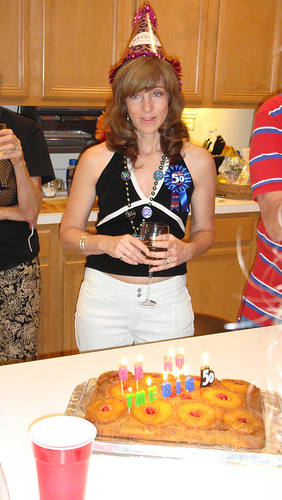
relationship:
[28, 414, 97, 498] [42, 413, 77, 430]
cup with inside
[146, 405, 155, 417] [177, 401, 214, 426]
cherry middle of pineapple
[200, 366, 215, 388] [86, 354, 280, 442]
50 on cake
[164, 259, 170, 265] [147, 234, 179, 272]
ring on left hand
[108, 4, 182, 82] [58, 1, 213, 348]
birthday hat on head of woman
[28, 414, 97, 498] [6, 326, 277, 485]
cup on top of table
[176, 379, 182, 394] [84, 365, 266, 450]
candle on top of birthday cake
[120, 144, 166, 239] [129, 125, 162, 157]
beads around neck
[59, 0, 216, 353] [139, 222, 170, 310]
girl holding glass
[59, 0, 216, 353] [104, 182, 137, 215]
girl wearing a shirt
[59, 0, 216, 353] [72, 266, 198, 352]
girl wearing pants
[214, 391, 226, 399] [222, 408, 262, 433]
cherry inside of slice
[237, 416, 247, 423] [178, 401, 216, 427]
cherry inside of slice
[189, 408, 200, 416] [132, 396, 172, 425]
cherry inside of slice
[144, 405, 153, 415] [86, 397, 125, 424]
cherry inside of slice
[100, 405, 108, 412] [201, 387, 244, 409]
cherry inside of slice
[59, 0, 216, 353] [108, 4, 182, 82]
girl wearing a birthday hat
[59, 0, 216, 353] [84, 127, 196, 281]
girl wearing a shirt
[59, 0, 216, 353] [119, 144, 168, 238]
girl wearing a necklace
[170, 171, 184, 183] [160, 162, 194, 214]
50 printed on ribbon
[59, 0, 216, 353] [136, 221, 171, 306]
girl holding glass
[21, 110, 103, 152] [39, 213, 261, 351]
toaster above cabinet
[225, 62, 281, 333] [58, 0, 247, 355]
person standing right of woman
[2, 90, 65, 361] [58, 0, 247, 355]
person standing left of woman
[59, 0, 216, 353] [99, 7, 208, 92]
girl wearing a hat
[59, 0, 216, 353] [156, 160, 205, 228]
girl wearing a ribbon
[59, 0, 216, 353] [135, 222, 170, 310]
girl holding glass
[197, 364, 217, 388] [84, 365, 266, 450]
candle on top of birthday cake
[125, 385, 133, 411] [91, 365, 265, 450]
candle on birthday cake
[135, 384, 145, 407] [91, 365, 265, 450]
candle on birthday cake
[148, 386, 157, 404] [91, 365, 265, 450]
candle on birthday cake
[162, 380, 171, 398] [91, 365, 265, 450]
candle on birthday cake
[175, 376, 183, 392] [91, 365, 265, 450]
candle on birthday cake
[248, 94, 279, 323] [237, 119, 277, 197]
shirt with stripes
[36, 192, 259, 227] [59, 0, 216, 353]
countertop in front of girl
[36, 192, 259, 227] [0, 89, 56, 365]
countertop in front of person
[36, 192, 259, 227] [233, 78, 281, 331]
countertop in front of person